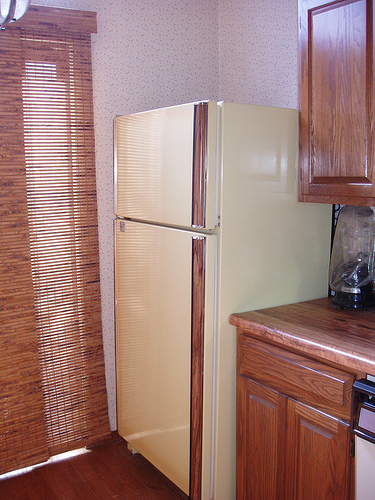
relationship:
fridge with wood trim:
[105, 99, 334, 496] [190, 102, 209, 227]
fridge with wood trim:
[105, 99, 334, 496] [191, 233, 204, 498]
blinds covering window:
[0, 5, 112, 473] [12, 54, 99, 273]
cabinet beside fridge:
[227, 296, 356, 499] [105, 99, 334, 496]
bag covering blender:
[332, 207, 372, 288] [322, 201, 374, 315]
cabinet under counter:
[295, 1, 375, 208] [226, 292, 375, 381]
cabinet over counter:
[294, 1, 373, 212] [226, 292, 375, 381]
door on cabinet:
[285, 400, 356, 493] [231, 338, 357, 498]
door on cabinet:
[231, 377, 283, 498] [231, 338, 357, 498]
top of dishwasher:
[351, 377, 372, 398] [347, 373, 372, 498]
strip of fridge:
[205, 102, 220, 432] [114, 107, 239, 498]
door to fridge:
[111, 98, 216, 235] [105, 99, 334, 496]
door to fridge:
[112, 215, 213, 498] [105, 99, 334, 496]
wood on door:
[188, 236, 206, 498] [112, 215, 205, 500]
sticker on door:
[118, 221, 126, 232] [93, 206, 246, 480]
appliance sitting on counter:
[321, 203, 374, 312] [227, 293, 373, 374]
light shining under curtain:
[0, 448, 95, 483] [2, 2, 109, 477]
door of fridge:
[111, 100, 208, 235] [100, 109, 210, 473]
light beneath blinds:
[0, 448, 95, 479] [0, 16, 94, 469]